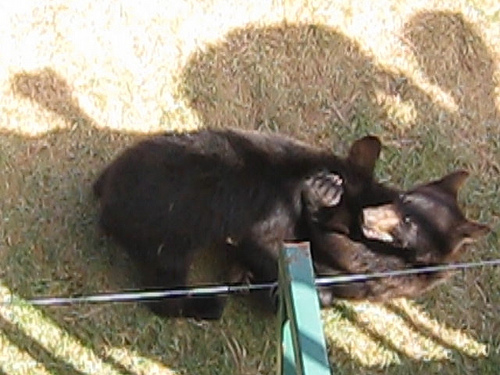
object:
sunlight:
[43, 5, 171, 118]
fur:
[134, 156, 238, 209]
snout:
[358, 199, 398, 229]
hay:
[291, 25, 437, 110]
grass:
[13, 323, 153, 372]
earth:
[78, 38, 462, 108]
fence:
[0, 240, 500, 375]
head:
[356, 168, 476, 255]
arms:
[301, 169, 374, 273]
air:
[68, 30, 337, 117]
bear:
[94, 123, 491, 320]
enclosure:
[0, 227, 500, 372]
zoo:
[0, 0, 500, 375]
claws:
[299, 157, 354, 210]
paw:
[196, 284, 233, 327]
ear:
[427, 168, 472, 192]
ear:
[351, 133, 388, 165]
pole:
[278, 242, 330, 375]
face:
[361, 189, 470, 256]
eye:
[398, 215, 415, 227]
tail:
[90, 165, 128, 207]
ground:
[22, 20, 397, 124]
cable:
[1, 261, 500, 306]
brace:
[267, 241, 330, 375]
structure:
[275, 241, 334, 375]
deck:
[10, 264, 250, 310]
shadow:
[0, 10, 499, 375]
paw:
[304, 171, 346, 207]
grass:
[113, 20, 360, 123]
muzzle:
[359, 204, 405, 240]